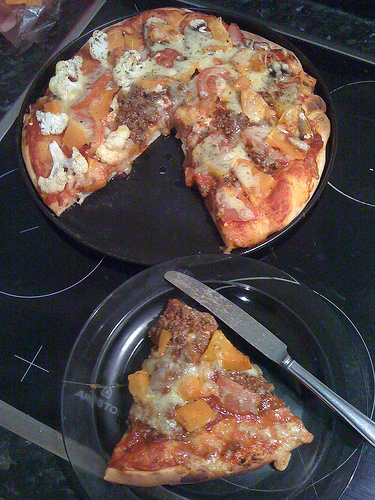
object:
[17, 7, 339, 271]
tray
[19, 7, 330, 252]
pizza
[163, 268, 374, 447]
knife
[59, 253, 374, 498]
plate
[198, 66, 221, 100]
tomato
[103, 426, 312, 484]
crust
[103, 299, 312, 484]
pizza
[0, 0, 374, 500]
table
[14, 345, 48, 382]
ex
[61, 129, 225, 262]
section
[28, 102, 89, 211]
sauce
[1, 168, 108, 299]
circle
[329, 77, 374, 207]
circle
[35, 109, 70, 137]
cauliflower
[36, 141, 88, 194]
cauliflower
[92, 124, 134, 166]
cauliflower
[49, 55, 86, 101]
cauliflower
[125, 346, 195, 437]
cheese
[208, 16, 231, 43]
pepper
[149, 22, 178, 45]
pepper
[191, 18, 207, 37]
mushroom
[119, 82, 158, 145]
sausage